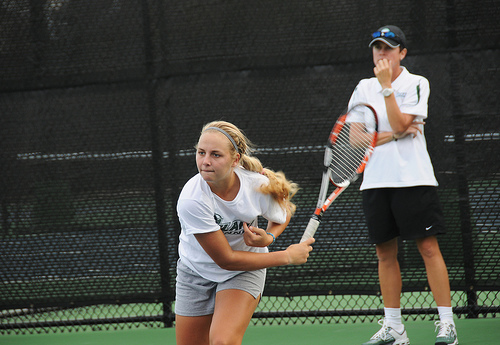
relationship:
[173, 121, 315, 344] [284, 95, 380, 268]
girl holding racket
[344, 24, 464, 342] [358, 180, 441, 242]
man wearing shorts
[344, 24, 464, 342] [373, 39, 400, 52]
man wearing sunglasses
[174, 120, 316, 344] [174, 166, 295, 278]
lady wearing shirt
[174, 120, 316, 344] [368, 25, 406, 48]
lady wearing baseball cap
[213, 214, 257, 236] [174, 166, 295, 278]
logo on shirt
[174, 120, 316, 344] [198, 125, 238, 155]
lady wearing headband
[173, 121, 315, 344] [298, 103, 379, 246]
girl swinging racket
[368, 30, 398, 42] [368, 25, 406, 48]
glasses on baseball cap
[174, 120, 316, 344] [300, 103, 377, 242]
lady holding racket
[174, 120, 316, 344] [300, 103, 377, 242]
lady swinging racket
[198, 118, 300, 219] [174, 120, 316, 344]
hair belonging to lady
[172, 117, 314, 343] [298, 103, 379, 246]
lady holding racket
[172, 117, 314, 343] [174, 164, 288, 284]
lady wearing shirt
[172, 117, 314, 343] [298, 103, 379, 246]
lady swinging racket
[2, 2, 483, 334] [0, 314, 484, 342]
fence lining tennis court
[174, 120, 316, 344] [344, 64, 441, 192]
lady wearing shirt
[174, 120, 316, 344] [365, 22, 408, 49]
lady wearing hat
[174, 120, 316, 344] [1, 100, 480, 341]
lady watching tennis game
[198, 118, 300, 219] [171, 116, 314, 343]
hair belonging to girl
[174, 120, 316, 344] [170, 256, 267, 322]
lady wearing shorts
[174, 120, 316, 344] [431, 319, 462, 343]
lady wearing shoe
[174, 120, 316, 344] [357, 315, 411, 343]
lady wearing shoe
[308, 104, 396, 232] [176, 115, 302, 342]
racket on woman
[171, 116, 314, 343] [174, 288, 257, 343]
girl has thighs